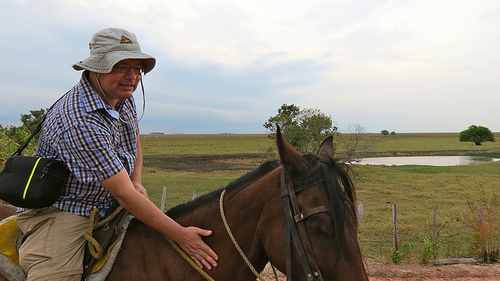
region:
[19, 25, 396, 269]
a man riding a horse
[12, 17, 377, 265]
a man petting a horse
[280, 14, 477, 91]
thick white clouds in the sky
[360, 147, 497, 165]
a small pond in a field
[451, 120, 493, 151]
a trees nest to the pond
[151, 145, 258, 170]
a patch of back dirt in the field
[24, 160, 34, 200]
a yellow stripe on a black bag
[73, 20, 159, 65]
a tan hat on head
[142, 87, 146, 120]
a hat strap dangling down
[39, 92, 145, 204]
a blue and yellow plaid shirt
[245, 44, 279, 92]
part of a cloud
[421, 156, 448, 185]
part of a ground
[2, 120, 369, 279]
A brown horse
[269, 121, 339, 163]
The ears of the horse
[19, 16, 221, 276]
A man riding the horse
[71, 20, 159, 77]
A grey hat on the head of the man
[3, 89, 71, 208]
A black shoulder bag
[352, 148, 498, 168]
A body of water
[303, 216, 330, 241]
The eye of the horse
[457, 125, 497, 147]
A tree in the background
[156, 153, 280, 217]
The black mane of the horse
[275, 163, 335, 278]
A leather horse harness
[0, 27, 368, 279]
an older man on his brown horse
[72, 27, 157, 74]
floppy hat is khaki colored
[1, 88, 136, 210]
a black canvas bag slung over the shoulder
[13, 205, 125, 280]
khaki cargo pants over a brown leather saddle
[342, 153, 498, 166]
a calm lake in the distance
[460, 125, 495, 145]
a leafy green shade tree in the distance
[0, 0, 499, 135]
cloudy blue sky atop the horizon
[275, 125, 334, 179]
long brown ears are alert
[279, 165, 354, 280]
leather head gear for leading horses around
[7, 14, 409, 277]
a man on a horse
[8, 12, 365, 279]
a man patting a horse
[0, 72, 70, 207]
a black bag with a yellow stripe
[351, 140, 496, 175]
a pond in a field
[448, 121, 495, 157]
a tree in a field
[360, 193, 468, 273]
a fence near a field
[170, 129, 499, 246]
a field behind a horse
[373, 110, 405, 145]
Trees in the distance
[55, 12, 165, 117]
a hat on a man